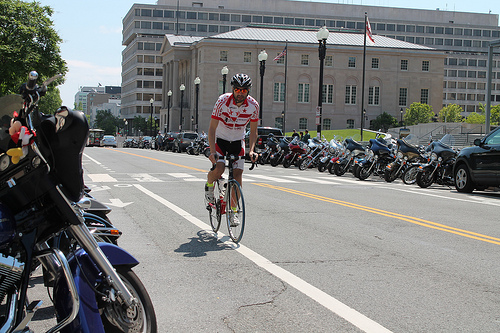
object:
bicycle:
[204, 147, 258, 244]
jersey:
[211, 93, 260, 142]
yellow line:
[102, 145, 500, 245]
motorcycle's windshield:
[441, 134, 455, 149]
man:
[205, 73, 260, 226]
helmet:
[230, 73, 253, 103]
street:
[76, 147, 499, 333]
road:
[80, 145, 499, 333]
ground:
[79, 147, 500, 333]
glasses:
[234, 87, 250, 94]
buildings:
[72, 0, 500, 147]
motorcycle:
[123, 127, 459, 190]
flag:
[363, 15, 376, 43]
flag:
[274, 46, 287, 62]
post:
[359, 10, 367, 140]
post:
[283, 38, 287, 136]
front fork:
[38, 187, 158, 333]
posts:
[149, 26, 329, 140]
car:
[453, 126, 500, 193]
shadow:
[174, 229, 240, 257]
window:
[399, 88, 408, 107]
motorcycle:
[0, 71, 157, 333]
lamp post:
[313, 28, 329, 140]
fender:
[53, 241, 140, 333]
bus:
[86, 128, 106, 146]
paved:
[155, 188, 462, 294]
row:
[105, 119, 500, 195]